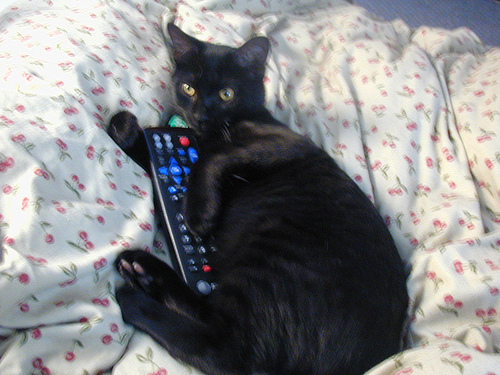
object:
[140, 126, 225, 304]
remote control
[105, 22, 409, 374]
cat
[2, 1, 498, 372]
blanket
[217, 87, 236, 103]
eye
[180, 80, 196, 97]
eye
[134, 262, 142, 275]
paw pad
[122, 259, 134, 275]
paw pad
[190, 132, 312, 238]
foreleg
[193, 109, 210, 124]
nose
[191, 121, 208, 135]
mouth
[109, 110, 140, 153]
right forepaw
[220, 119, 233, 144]
left whiskers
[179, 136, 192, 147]
button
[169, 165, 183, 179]
button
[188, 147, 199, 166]
button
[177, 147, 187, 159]
button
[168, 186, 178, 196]
button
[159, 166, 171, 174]
button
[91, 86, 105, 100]
cherry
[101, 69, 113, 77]
cherry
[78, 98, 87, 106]
cherry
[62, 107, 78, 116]
cherry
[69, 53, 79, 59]
cherry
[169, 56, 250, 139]
face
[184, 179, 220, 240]
paw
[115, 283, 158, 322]
back paw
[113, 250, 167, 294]
back paw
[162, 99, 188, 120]
whiskers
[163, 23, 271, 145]
head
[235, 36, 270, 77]
ear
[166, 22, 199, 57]
ear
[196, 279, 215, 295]
button